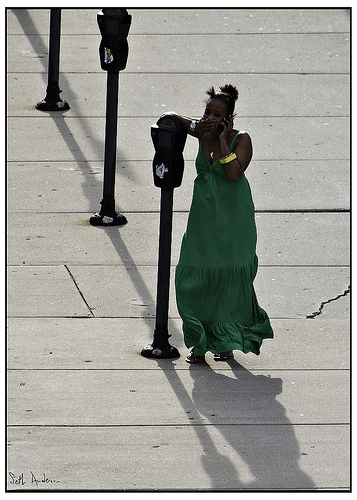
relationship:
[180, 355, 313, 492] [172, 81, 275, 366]
shadow of woman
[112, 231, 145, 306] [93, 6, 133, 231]
shadow of meter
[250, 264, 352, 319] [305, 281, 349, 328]
tile has crack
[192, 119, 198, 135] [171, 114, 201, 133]
wrist watch on arm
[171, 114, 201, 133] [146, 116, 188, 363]
arm on meter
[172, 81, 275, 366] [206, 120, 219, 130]
woman covering mouth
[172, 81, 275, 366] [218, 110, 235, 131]
woman holding cellphone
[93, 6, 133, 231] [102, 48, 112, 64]
meter with label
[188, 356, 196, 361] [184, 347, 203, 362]
toes in sandals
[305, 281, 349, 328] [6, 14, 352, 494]
crack in ground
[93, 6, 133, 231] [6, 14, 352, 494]
meter on walkway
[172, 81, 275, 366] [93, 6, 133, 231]
woman against meter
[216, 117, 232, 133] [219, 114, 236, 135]
cell phone in hand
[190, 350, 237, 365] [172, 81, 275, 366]
sandals on woman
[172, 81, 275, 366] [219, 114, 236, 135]
woman with hand